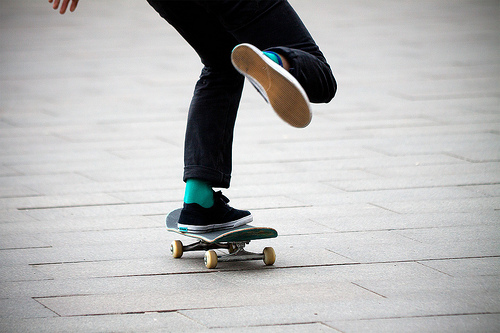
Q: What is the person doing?
A: Skateboarding?.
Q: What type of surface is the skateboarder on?
A: Brick.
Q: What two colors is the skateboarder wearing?
A: Black and turquoise.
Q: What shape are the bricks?
A: Rectangle.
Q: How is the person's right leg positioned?
A: It's bent.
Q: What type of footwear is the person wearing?
A: Sneakers.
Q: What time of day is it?
A: Morning.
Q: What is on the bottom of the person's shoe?
A: Dirt.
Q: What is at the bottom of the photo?
A: The floor.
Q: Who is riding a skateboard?
A: A person.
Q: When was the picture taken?
A: Daytime.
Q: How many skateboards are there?
A: One.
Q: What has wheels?
A: A skateboard.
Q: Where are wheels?
A: On a skateboard.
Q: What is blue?
A: Socks.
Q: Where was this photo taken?
A: On a brick walkway.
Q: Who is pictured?
A: A skateboarder.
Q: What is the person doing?
A: Skateboarding.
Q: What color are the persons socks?
A: Teal.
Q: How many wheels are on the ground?
A: 4.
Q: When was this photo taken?
A: During the day.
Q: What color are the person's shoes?
A: They are black.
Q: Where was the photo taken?
A: On the sidewalk.